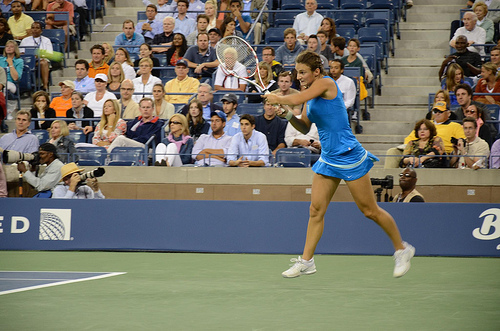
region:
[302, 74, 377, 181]
a blue tennis dress on a woman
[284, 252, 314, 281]
a white tennis shoe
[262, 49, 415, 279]
a woman jumping in the air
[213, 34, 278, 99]
a tennis racket in a woman's hands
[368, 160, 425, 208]
a camera man on the side of a tennis court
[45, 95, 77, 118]
an orange shirt on a man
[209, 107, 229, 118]
a blue cap on a man's head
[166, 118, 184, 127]
sunglasses on a woman's face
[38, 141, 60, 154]
a black cap on a man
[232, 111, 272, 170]
PErson sitting in the stands watching a tennis game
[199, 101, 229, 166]
PErson sitting in the stands watching a tennis game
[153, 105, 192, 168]
PErson sitting in the stands watching a tennis game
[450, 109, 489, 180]
PErson sitting in the stands watching a tennis game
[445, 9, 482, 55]
PErson sitting in the stands watching a tennis game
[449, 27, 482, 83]
PErson sitting in the stands watching a tennis game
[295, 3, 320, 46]
PErson sitting in the stands watching a tennis game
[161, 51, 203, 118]
PErson sitting in the stands watching a tennis game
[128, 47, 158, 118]
PErson sitting in the stands watching a tennis game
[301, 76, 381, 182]
a blue tennis dress on a woman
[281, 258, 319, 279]
a white tennis shoe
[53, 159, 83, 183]
a yellow hat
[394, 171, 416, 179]
sunglasses on a man's face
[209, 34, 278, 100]
a tennis racket in a woman's hands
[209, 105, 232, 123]
a blue cap on a man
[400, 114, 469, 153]
a yellow shirt on a man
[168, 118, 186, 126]
sunglasses on a woman's face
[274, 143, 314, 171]
an empty blue chair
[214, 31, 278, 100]
a red and white racket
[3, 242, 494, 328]
part of a tennis court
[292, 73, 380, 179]
a woman's blue tennis dress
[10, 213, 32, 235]
a white capital letter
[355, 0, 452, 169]
part of a stadium stairway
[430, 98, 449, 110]
a yellow baseball cap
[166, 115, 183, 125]
dark black sunglasses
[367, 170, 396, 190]
part of a long black camera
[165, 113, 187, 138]
a woman's blonde hair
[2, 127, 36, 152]
a man's blue shirt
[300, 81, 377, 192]
the tennis uniform is blue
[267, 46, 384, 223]
the tennis uniform is blue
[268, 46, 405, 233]
the tennis uniform is blue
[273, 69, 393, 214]
the tennis uniform is blue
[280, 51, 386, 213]
the tennis uniform is blue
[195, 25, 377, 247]
player is holding a racket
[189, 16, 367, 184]
player is holding a racket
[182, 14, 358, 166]
player is holding a racket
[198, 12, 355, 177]
player is holding a racket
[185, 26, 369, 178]
player is holding a racket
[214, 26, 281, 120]
a woman holding a tennis racket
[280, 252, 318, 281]
a woman wearing white shoes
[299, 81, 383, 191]
a woman wearing a blue tennis suit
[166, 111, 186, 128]
a woman wearing sunglasses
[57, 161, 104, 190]
a person holding camera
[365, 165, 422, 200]
a man holding a camera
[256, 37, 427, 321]
a woman jumping off the ground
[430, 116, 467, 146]
a man wearing a yellow shirt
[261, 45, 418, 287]
girl in a tennis match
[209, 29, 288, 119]
racket in a girl's hand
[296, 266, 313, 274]
grey colored nike swoosh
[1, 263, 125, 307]
blue area of the court